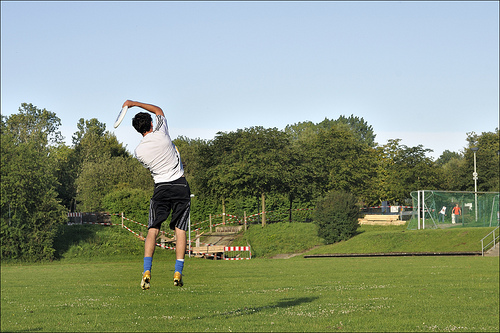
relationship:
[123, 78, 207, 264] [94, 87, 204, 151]
boy in air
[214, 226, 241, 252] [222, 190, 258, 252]
white and orange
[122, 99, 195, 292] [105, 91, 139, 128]
boy with frisbee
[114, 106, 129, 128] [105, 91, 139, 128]
frisbee white frisbee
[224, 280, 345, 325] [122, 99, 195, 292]
shadow of boy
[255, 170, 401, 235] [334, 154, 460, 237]
large taped area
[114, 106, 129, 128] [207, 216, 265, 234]
frisbee section railing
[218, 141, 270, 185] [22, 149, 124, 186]
thick row trees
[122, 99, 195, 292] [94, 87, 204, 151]
boy in air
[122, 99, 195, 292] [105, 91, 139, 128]
boy has frisbee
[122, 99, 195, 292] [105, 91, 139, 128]
boy flying frisbee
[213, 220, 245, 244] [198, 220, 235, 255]
bridge area background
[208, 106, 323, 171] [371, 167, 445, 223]
green net distance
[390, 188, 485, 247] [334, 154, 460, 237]
people far away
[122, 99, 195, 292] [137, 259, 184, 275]
boy wearing socks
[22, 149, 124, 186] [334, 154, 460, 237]
trees in area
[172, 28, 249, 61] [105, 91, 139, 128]
clear skies frisbee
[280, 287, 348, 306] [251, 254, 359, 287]
patch of green grass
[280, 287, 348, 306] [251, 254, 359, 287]
patch of grass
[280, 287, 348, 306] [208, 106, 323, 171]
patch of green